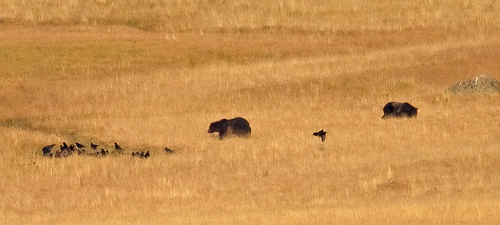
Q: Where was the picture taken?
A: It was taken at the pasture.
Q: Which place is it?
A: It is a pasture.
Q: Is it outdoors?
A: Yes, it is outdoors.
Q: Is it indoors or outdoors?
A: It is outdoors.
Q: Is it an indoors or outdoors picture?
A: It is outdoors.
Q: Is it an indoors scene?
A: No, it is outdoors.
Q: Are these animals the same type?
A: No, there are both birds and bears.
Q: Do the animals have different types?
A: Yes, they are birds and bears.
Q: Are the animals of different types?
A: Yes, they are birds and bears.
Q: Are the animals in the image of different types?
A: Yes, they are birds and bears.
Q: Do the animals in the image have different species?
A: Yes, they are birds and bears.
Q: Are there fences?
A: No, there are no fences.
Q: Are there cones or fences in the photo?
A: No, there are no fences or cones.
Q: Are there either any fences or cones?
A: No, there are no fences or cones.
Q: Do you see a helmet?
A: No, there are no helmets.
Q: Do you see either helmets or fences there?
A: No, there are no helmets or fences.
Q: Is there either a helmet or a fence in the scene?
A: No, there are no helmets or fences.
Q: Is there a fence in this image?
A: No, there are no fences.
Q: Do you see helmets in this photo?
A: No, there are no helmets.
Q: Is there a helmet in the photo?
A: No, there are no helmets.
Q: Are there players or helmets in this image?
A: No, there are no helmets or players.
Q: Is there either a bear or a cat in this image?
A: Yes, there is a bear.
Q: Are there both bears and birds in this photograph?
A: Yes, there are both a bear and a bird.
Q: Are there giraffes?
A: No, there are no giraffes.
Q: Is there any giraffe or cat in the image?
A: No, there are no giraffes or cats.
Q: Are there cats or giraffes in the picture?
A: No, there are no giraffes or cats.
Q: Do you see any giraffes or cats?
A: No, there are no giraffes or cats.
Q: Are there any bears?
A: Yes, there is a bear.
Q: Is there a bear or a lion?
A: Yes, there is a bear.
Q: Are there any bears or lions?
A: Yes, there is a bear.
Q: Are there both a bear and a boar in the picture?
A: No, there is a bear but no boars.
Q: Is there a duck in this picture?
A: No, there are no ducks.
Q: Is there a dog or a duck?
A: No, there are no ducks or dogs.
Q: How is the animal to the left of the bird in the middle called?
A: The animal is a bear.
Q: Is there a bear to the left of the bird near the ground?
A: Yes, there is a bear to the left of the bird.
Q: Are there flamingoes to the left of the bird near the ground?
A: No, there is a bear to the left of the bird.